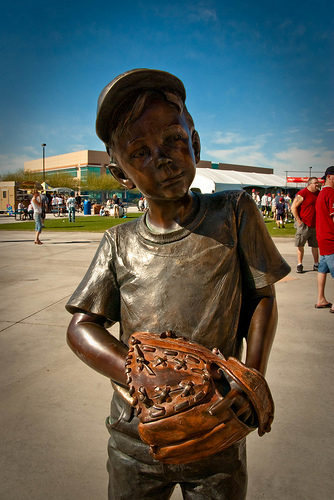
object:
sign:
[286, 176, 325, 183]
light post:
[41, 143, 47, 182]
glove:
[125, 327, 276, 467]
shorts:
[294, 220, 317, 248]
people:
[16, 178, 294, 222]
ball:
[128, 330, 275, 465]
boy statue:
[66, 66, 290, 500]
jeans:
[105, 391, 249, 500]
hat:
[93, 67, 187, 137]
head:
[94, 67, 201, 204]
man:
[313, 165, 334, 315]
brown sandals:
[314, 302, 332, 309]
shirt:
[31, 196, 42, 215]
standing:
[30, 187, 46, 246]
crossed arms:
[33, 195, 43, 208]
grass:
[63, 213, 97, 233]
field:
[1, 174, 334, 419]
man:
[290, 176, 322, 273]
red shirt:
[294, 188, 323, 228]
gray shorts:
[294, 219, 318, 247]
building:
[20, 149, 295, 207]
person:
[31, 189, 44, 244]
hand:
[298, 221, 302, 227]